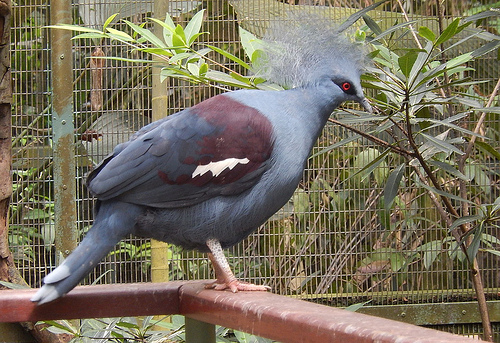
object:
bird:
[30, 7, 371, 304]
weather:
[0, 7, 500, 84]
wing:
[81, 94, 265, 207]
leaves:
[39, 5, 236, 87]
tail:
[29, 203, 138, 304]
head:
[321, 60, 374, 116]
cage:
[0, 0, 498, 341]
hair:
[261, 14, 368, 85]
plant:
[41, 0, 493, 340]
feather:
[29, 213, 136, 306]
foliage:
[40, 13, 131, 45]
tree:
[42, 2, 499, 341]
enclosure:
[1, 0, 498, 342]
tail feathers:
[31, 192, 144, 305]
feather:
[192, 157, 250, 180]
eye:
[342, 82, 351, 91]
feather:
[84, 126, 149, 200]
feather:
[30, 264, 69, 306]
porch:
[0, 263, 490, 343]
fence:
[309, 153, 391, 295]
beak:
[357, 94, 374, 113]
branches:
[40, 8, 418, 163]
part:
[216, 128, 251, 152]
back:
[204, 239, 239, 281]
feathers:
[160, 96, 271, 196]